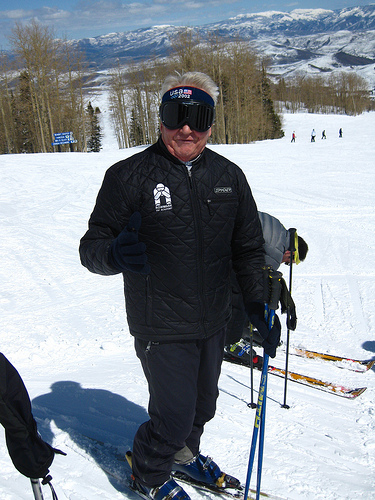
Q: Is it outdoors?
A: Yes, it is outdoors.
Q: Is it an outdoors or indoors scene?
A: It is outdoors.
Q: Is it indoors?
A: No, it is outdoors.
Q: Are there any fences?
A: No, there are no fences.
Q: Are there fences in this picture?
A: No, there are no fences.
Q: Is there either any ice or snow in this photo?
A: Yes, there is snow.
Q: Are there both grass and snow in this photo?
A: No, there is snow but no grass.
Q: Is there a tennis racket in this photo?
A: No, there are no rackets.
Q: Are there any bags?
A: No, there are no bags.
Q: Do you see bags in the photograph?
A: No, there are no bags.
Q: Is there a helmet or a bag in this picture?
A: No, there are no bags or helmets.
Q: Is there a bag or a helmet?
A: No, there are no bags or helmets.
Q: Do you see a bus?
A: No, there are no buses.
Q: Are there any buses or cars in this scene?
A: No, there are no buses or cars.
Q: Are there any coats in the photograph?
A: Yes, there is a coat.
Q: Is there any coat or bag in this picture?
A: Yes, there is a coat.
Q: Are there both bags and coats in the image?
A: No, there is a coat but no bags.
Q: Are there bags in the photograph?
A: No, there are no bags.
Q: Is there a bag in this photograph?
A: No, there are no bags.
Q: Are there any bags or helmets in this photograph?
A: No, there are no bags or helmets.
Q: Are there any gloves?
A: Yes, there are gloves.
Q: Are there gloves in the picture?
A: Yes, there are gloves.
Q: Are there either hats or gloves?
A: Yes, there are gloves.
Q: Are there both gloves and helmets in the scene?
A: No, there are gloves but no helmets.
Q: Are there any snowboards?
A: No, there are no snowboards.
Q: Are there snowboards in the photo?
A: No, there are no snowboards.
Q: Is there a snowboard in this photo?
A: No, there are no snowboards.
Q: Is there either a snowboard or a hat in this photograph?
A: No, there are no snowboards or hats.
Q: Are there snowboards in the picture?
A: No, there are no snowboards.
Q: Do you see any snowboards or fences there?
A: No, there are no snowboards or fences.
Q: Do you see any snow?
A: Yes, there is snow.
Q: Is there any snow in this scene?
A: Yes, there is snow.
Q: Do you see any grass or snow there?
A: Yes, there is snow.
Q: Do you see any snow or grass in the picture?
A: Yes, there is snow.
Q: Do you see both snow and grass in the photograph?
A: No, there is snow but no grass.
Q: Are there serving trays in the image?
A: No, there are no serving trays.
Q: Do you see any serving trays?
A: No, there are no serving trays.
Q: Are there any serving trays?
A: No, there are no serving trays.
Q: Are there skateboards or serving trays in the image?
A: No, there are no serving trays or skateboards.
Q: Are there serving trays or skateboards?
A: No, there are no serving trays or skateboards.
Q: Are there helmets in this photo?
A: No, there are no helmets.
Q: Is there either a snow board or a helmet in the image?
A: No, there are no helmets or snowboards.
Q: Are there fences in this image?
A: No, there are no fences.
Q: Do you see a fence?
A: No, there are no fences.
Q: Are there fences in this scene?
A: No, there are no fences.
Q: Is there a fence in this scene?
A: No, there are no fences.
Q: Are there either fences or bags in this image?
A: No, there are no fences or bags.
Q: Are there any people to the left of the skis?
A: Yes, there is a person to the left of the skis.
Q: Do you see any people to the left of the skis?
A: Yes, there is a person to the left of the skis.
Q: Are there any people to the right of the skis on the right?
A: No, the person is to the left of the skis.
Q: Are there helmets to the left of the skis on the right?
A: No, there is a person to the left of the skis.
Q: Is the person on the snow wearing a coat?
A: Yes, the person is wearing a coat.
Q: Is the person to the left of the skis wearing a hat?
A: No, the person is wearing a coat.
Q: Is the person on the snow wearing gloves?
A: Yes, the person is wearing gloves.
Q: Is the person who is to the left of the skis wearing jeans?
A: No, the person is wearing gloves.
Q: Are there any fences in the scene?
A: No, there are no fences.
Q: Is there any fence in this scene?
A: No, there are no fences.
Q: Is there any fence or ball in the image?
A: No, there are no fences or balls.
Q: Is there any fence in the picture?
A: No, there are no fences.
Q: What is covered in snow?
A: The ground is covered in snow.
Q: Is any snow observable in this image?
A: Yes, there is snow.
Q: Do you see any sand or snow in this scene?
A: Yes, there is snow.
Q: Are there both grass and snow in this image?
A: No, there is snow but no grass.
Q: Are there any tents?
A: No, there are no tents.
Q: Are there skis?
A: Yes, there are skis.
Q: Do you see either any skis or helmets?
A: Yes, there are skis.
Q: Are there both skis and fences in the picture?
A: No, there are skis but no fences.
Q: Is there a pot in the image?
A: No, there are no pots.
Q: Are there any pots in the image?
A: No, there are no pots.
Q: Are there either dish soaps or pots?
A: No, there are no pots or dish soaps.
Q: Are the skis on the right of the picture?
A: Yes, the skis are on the right of the image.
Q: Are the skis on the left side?
A: No, the skis are on the right of the image.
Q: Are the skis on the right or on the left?
A: The skis are on the right of the image.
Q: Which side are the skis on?
A: The skis are on the right of the image.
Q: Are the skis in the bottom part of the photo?
A: Yes, the skis are in the bottom of the image.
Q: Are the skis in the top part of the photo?
A: No, the skis are in the bottom of the image.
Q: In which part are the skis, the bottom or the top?
A: The skis are in the bottom of the image.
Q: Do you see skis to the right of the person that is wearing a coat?
A: Yes, there are skis to the right of the person.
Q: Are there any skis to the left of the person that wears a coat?
A: No, the skis are to the right of the person.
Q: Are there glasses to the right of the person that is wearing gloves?
A: No, there are skis to the right of the person.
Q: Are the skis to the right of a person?
A: Yes, the skis are to the right of a person.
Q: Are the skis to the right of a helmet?
A: No, the skis are to the right of a person.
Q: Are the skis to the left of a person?
A: No, the skis are to the right of a person.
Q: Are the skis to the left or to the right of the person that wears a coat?
A: The skis are to the right of the person.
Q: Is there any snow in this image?
A: Yes, there is snow.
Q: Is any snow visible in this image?
A: Yes, there is snow.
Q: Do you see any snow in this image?
A: Yes, there is snow.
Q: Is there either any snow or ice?
A: Yes, there is snow.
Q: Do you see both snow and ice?
A: No, there is snow but no ice.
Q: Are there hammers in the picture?
A: No, there are no hammers.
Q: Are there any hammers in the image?
A: No, there are no hammers.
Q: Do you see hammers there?
A: No, there are no hammers.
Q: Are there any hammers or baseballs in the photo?
A: No, there are no hammers or baseballs.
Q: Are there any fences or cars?
A: No, there are no fences or cars.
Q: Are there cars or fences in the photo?
A: No, there are no fences or cars.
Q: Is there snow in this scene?
A: Yes, there is snow.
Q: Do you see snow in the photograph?
A: Yes, there is snow.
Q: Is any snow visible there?
A: Yes, there is snow.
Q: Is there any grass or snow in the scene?
A: Yes, there is snow.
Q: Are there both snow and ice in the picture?
A: No, there is snow but no ice.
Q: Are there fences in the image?
A: No, there are no fences.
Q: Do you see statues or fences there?
A: No, there are no fences or statues.